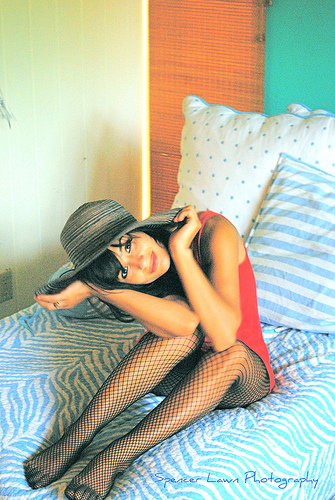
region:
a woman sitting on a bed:
[22, 195, 278, 496]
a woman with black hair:
[78, 224, 167, 298]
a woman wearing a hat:
[38, 194, 184, 302]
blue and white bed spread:
[216, 414, 318, 490]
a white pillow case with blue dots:
[178, 165, 265, 198]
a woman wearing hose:
[149, 361, 241, 463]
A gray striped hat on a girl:
[37, 198, 184, 295]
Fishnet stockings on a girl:
[22, 343, 280, 498]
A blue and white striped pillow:
[252, 153, 333, 335]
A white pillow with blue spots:
[176, 97, 333, 237]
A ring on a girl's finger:
[50, 303, 61, 309]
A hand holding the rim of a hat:
[168, 204, 203, 246]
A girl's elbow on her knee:
[212, 342, 236, 353]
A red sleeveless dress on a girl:
[196, 209, 279, 392]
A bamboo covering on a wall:
[145, 2, 265, 210]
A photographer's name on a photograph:
[156, 465, 321, 493]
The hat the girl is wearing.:
[31, 190, 191, 294]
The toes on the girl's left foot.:
[22, 457, 46, 488]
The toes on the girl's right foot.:
[64, 485, 94, 499]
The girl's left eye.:
[120, 263, 128, 276]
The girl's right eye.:
[126, 239, 132, 250]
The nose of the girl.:
[136, 255, 147, 270]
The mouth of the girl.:
[150, 250, 157, 274]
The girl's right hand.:
[169, 206, 202, 250]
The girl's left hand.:
[34, 280, 91, 312]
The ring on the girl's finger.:
[54, 299, 61, 310]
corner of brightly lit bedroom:
[2, 0, 334, 497]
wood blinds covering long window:
[148, 0, 267, 215]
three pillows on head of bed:
[0, 95, 333, 497]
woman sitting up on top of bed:
[0, 197, 333, 498]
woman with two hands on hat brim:
[25, 198, 275, 497]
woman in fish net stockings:
[25, 198, 273, 497]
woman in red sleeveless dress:
[25, 197, 272, 498]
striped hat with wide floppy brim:
[34, 197, 182, 300]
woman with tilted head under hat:
[24, 198, 272, 498]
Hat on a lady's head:
[28, 192, 189, 296]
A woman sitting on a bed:
[0, 86, 331, 494]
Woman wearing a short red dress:
[25, 190, 278, 395]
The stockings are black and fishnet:
[18, 324, 266, 494]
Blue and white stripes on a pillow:
[236, 144, 329, 336]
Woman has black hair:
[74, 220, 186, 327]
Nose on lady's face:
[127, 250, 146, 270]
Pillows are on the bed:
[160, 88, 329, 336]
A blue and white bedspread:
[0, 294, 330, 495]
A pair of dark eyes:
[114, 233, 134, 284]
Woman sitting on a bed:
[21, 196, 274, 498]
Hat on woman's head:
[31, 197, 183, 300]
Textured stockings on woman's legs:
[23, 334, 268, 497]